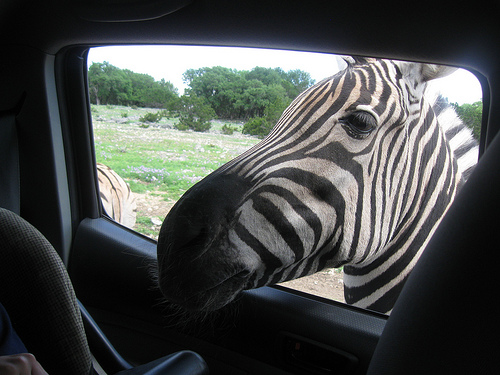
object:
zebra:
[156, 53, 480, 317]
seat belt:
[0, 110, 21, 217]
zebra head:
[157, 54, 481, 316]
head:
[156, 53, 459, 310]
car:
[0, 0, 500, 373]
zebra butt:
[95, 159, 137, 231]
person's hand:
[1, 351, 46, 374]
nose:
[170, 192, 220, 264]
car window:
[86, 45, 482, 318]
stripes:
[233, 212, 284, 287]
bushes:
[157, 88, 222, 130]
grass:
[91, 103, 263, 241]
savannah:
[82, 64, 484, 317]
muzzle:
[155, 205, 251, 312]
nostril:
[178, 215, 213, 252]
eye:
[343, 110, 377, 138]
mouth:
[156, 263, 249, 313]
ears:
[413, 62, 458, 83]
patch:
[131, 166, 165, 175]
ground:
[87, 106, 348, 304]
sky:
[87, 44, 484, 106]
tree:
[84, 61, 178, 107]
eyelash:
[355, 110, 376, 127]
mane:
[422, 83, 479, 181]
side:
[2, 209, 92, 372]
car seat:
[0, 208, 207, 374]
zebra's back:
[93, 162, 115, 180]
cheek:
[335, 166, 385, 211]